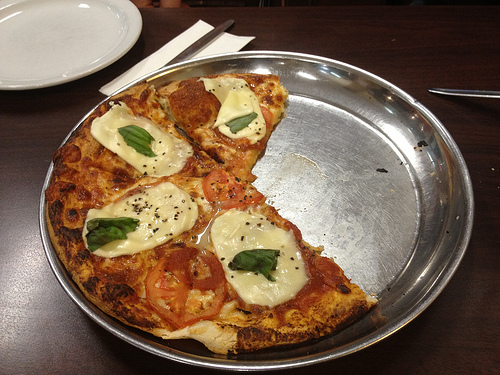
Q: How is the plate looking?
A: Round.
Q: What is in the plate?
A: Food.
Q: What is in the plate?
A: Metal.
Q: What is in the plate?
A: Pizza.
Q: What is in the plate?
A: Marks.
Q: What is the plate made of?
A: Glass.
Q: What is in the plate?
A: Napkin.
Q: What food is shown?
A: A Pizza.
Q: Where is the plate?
A: The left corner.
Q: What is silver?
A: The pizza tray.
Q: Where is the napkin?
A: Above the tray.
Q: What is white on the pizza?
A: Cheese.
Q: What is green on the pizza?
A: Basil.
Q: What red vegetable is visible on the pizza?
A: Tomato.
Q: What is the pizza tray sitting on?
A: A table.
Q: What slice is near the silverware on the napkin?
A: The slice near the top of the plate.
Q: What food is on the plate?
A: There is a pizza on the plate.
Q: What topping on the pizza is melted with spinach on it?
A: A slice of mozzarella cheese is on top of the slices.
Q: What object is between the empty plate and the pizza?
A: There is a utensil on a napkin.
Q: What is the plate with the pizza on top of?
A: The pizza plate is on top of a wooden table.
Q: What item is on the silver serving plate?
A: A pizza.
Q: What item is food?
A: The pizza.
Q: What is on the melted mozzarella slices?
A: There is seasoning on the mozzarella.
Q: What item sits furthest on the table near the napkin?
A: A empty plate.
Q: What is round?
A: Plates.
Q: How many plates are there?
A: Two.